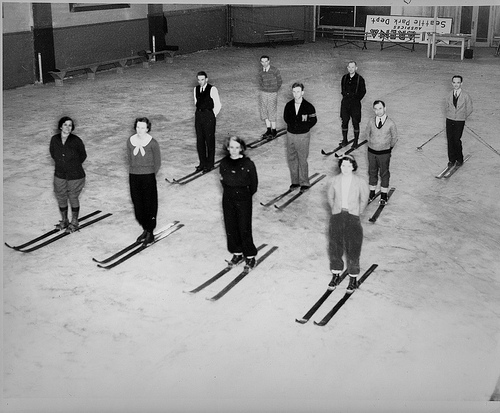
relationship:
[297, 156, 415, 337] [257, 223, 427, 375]
ski on snow